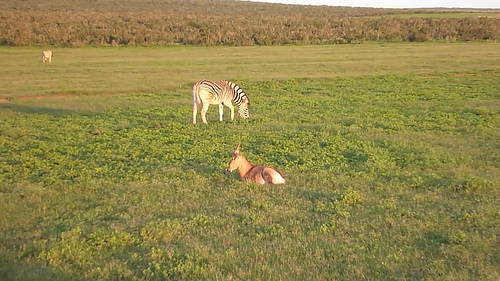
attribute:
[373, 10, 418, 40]
leaves — drying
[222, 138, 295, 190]
antelope — laying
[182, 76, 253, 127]
animal — laying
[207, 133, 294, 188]
antelope — resting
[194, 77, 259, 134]
zebra — black and white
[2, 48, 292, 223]
animals — wild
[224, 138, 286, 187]
antelope — laying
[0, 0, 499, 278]
field — grassy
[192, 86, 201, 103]
tail — long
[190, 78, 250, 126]
zebra — eating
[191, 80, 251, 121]
zebra — standing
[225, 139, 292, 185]
animal — brown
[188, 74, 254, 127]
zebra — grazing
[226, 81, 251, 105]
mane — zebra's, long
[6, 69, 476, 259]
field — grassy